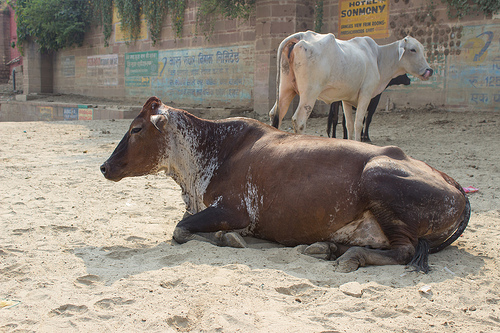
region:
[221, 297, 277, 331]
ground covered in sand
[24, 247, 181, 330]
animal tracks in sand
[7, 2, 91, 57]
shrubs with green leaves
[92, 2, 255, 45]
green vines hanging down wall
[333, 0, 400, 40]
yellow sign on wall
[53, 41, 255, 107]
paintings on stone wall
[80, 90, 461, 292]
brown animal laying in sand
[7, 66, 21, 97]
blue metal post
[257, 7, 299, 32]
brown brick wall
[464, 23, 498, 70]
design on side of stone wall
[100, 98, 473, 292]
brown cow laying in sand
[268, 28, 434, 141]
white cow standing in sand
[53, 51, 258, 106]
advertisements painted on wall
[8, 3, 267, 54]
branches with green leaves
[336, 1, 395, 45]
yellow city rules sign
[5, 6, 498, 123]
red and grey cinder block wall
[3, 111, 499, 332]
sand covered walk way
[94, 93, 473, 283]
large cow resting in sand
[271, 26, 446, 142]
white cow looking for food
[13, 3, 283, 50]
ivy leaves hanging on wall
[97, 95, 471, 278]
brown cow lying down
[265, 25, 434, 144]
white cow standing up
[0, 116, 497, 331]
ground covered in sand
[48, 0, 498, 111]
faded advertisements on wall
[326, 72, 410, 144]
small black cow behind white cow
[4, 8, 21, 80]
red door on wall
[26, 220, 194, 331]
hoof prints in the sand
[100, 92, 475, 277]
white and brown cow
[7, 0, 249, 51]
vines on the wall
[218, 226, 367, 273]
cow hoofs in the sand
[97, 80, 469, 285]
brown cow laying in the sand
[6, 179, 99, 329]
sand underneath the cows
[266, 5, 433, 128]
white baby cow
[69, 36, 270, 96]
wall with writing on it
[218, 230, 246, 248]
brown cow hoof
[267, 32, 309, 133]
white cow tail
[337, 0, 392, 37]
yellow hotel advertisement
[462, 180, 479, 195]
litter on the sand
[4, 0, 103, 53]
green vegetation over the wall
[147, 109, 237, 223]
white spotted cow neck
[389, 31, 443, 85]
the white head of a cow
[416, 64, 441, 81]
the nose of a cow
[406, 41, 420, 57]
the eye of a cow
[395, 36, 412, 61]
the ear of a cow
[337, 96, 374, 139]
the front legs of a cow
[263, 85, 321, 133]
the rear legs of a cow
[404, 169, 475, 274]
the tail of a cow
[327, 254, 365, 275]
the hoof of a cow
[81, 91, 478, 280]
a large brown cow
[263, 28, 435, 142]
a small white cow